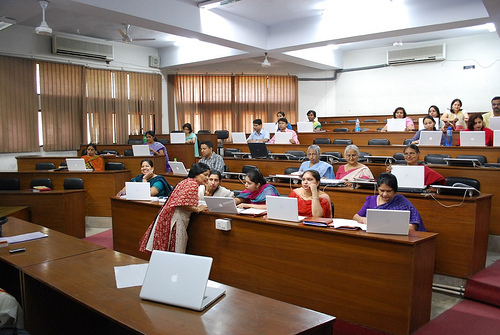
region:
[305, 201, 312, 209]
woman wearing red shirt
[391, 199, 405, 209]
woman wearing purple shirt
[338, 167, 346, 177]
woman wearing pink shirt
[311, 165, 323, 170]
woman wearing blue shirt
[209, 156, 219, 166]
man wearing striped shirt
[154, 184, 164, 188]
woman wearing green shirt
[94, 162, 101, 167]
woman wearing orange shirt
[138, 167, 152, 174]
smile on womans face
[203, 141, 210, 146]
man has black hair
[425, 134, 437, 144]
apple sign on laptop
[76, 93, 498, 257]
A bunch of adults in a classroom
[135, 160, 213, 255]
Female teacher leaning over a desk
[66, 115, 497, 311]
Many white laptop computers on desks in a classroom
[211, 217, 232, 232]
An electrical outlet on the side of a desk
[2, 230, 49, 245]
Paper sitting on a desk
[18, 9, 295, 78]
Ceiling fans in a classroom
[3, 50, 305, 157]
Brown pull shades on windows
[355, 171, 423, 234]
Woman wearing a bright purple shirt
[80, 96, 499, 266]
Classroom full of middle east ethinic people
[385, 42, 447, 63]
Wall mounted air conditioner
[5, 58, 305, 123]
windows on the wall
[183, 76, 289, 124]
curtains on the window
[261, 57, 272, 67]
a light hanging from the ceiling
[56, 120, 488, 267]
people sitting at desks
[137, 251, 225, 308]
a white laptop on the desk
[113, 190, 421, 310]
a wooden desk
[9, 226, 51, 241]
papers on the desk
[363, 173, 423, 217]
a woman in a purple shirt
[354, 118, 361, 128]
a water bottle on the desk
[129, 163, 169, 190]
a lady in a blue shirt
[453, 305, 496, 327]
dark red rug on stairs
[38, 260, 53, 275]
reflection on desk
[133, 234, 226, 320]
white laptop on table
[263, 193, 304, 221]
white laptop opened up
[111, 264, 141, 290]
white paper on desk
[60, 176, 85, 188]
black desk chair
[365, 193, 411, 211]
dark purple shirt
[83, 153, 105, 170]
bright orange shirt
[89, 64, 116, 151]
long brown window shades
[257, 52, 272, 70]
solid white light fixture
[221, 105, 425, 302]
a lot of students in a class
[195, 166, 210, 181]
the head of a woman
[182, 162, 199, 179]
the hair of a woman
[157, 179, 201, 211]
the sari of a woman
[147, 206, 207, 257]
the skirt of a woman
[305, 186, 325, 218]
the arm of a woman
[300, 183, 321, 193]
the hand of a woman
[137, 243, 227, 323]
a small white laptop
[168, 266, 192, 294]
the logo of a laptop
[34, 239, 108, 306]
the top of a desk